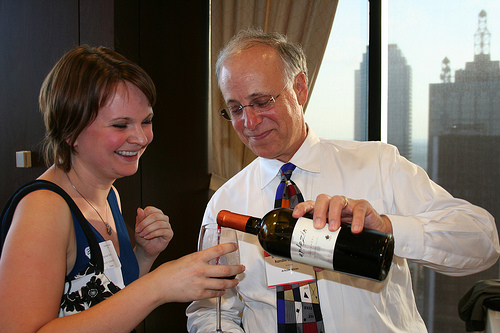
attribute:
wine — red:
[252, 228, 394, 281]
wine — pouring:
[217, 225, 222, 264]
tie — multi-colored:
[273, 162, 326, 333]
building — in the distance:
[430, 9, 499, 333]